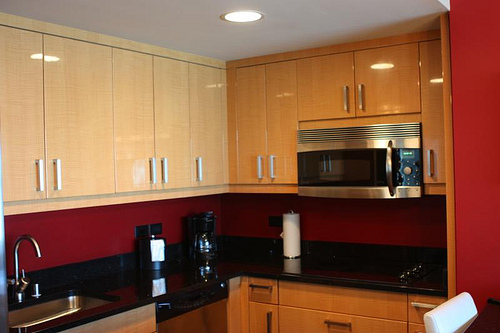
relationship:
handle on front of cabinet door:
[147, 155, 156, 186] [112, 46, 156, 192]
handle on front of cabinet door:
[195, 154, 204, 183] [188, 63, 224, 187]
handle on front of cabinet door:
[53, 156, 64, 194] [43, 32, 115, 201]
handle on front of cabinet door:
[158, 155, 169, 186] [153, 52, 193, 193]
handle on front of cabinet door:
[34, 155, 45, 195] [0, 25, 45, 202]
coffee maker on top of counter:
[179, 207, 219, 261] [7, 234, 446, 333]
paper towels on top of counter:
[280, 212, 302, 257] [7, 234, 446, 333]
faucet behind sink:
[13, 230, 41, 303] [5, 293, 113, 327]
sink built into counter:
[5, 293, 113, 327] [7, 234, 446, 333]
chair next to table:
[422, 289, 477, 332] [453, 296, 498, 332]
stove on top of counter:
[281, 252, 439, 284] [7, 234, 446, 333]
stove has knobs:
[281, 252, 439, 284] [396, 259, 424, 285]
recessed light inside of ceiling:
[222, 7, 261, 23] [0, 0, 449, 61]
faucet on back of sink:
[13, 230, 41, 303] [5, 293, 113, 327]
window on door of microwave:
[318, 155, 371, 182] [294, 121, 421, 199]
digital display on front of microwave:
[400, 149, 415, 159] [294, 121, 421, 199]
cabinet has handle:
[112, 47, 191, 196] [147, 155, 156, 186]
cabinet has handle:
[112, 47, 191, 196] [158, 155, 169, 186]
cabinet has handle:
[1, 25, 116, 205] [34, 155, 45, 195]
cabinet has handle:
[1, 25, 116, 205] [53, 156, 64, 194]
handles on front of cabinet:
[146, 152, 170, 187] [112, 47, 191, 196]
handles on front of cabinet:
[36, 155, 62, 194] [1, 25, 116, 205]